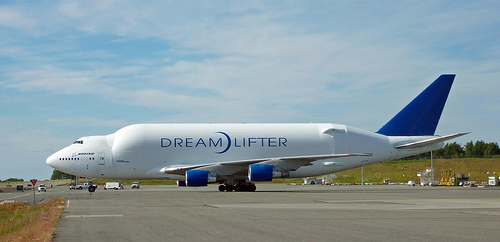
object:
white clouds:
[51, 33, 111, 103]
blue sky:
[0, 0, 500, 179]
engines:
[245, 160, 293, 183]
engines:
[183, 168, 230, 187]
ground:
[0, 134, 498, 242]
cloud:
[0, 55, 83, 107]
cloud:
[0, 3, 89, 50]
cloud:
[466, 89, 500, 141]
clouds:
[228, 83, 298, 113]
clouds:
[109, 89, 179, 119]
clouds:
[310, 82, 386, 120]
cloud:
[13, 58, 137, 96]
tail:
[378, 63, 458, 150]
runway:
[1, 182, 500, 242]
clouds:
[0, 139, 47, 174]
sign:
[29, 178, 38, 185]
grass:
[0, 195, 67, 238]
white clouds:
[284, 100, 379, 121]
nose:
[42, 142, 105, 178]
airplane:
[41, 70, 472, 193]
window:
[59, 158, 62, 161]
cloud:
[161, 26, 310, 78]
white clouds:
[207, 27, 377, 90]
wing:
[165, 151, 371, 177]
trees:
[482, 142, 500, 160]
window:
[80, 140, 84, 144]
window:
[88, 157, 92, 160]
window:
[92, 157, 94, 160]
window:
[77, 157, 80, 161]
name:
[157, 135, 295, 149]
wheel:
[87, 185, 95, 193]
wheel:
[217, 184, 225, 191]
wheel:
[226, 184, 234, 192]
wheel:
[248, 183, 257, 192]